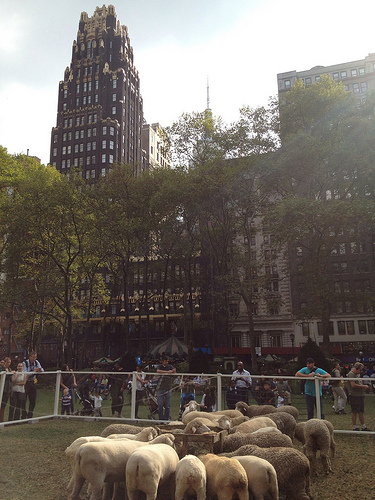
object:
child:
[59, 387, 73, 415]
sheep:
[126, 443, 181, 499]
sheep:
[175, 454, 208, 499]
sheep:
[197, 452, 250, 498]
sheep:
[241, 453, 279, 497]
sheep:
[223, 431, 295, 452]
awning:
[145, 335, 189, 356]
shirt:
[298, 366, 326, 397]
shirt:
[62, 394, 71, 406]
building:
[50, 3, 144, 192]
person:
[154, 355, 178, 421]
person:
[231, 361, 253, 405]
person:
[296, 357, 334, 421]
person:
[9, 361, 28, 420]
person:
[22, 350, 46, 420]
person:
[1, 357, 14, 423]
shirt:
[231, 369, 252, 389]